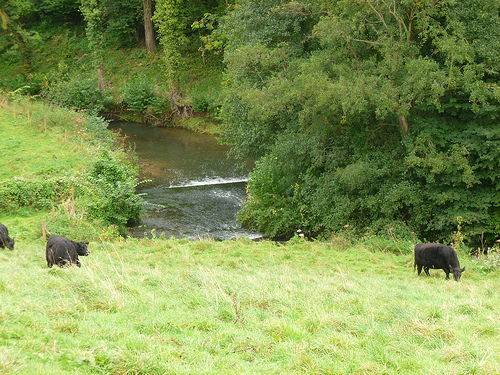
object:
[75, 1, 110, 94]
trees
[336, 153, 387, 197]
leaves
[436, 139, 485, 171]
ground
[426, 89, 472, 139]
ground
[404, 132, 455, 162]
ground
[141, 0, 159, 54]
tree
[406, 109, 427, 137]
ground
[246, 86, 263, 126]
wall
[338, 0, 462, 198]
tree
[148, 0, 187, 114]
tree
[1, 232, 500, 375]
field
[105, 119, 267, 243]
water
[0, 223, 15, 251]
cow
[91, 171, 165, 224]
fern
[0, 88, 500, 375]
grass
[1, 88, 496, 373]
bank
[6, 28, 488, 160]
bank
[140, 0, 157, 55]
tree trunk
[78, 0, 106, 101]
tree trunk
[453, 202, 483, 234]
leaf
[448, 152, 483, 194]
leaf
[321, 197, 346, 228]
leaf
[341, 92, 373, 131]
leaf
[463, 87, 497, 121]
leaf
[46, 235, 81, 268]
cow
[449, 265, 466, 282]
head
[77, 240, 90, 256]
head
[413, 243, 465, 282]
cow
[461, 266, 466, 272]
ear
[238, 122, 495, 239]
tree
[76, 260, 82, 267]
leg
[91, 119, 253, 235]
river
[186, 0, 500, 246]
forest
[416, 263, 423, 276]
leg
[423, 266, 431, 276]
leg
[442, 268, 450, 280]
leg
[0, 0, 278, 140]
hill